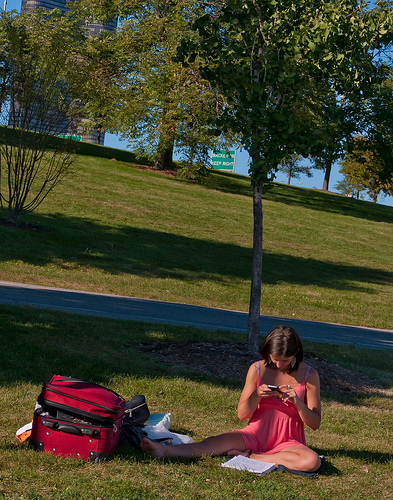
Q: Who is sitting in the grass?
A: A woman in a pink dress.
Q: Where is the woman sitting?
A: In the grass.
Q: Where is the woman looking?
A: At a cell phone.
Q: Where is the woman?
A: In a park.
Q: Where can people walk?
A: On the paved pathway.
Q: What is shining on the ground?
A: Sunlight.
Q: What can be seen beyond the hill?
A: A street sign.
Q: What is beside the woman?
A: A luggage case.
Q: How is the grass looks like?
A: Good.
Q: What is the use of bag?
A: To store items.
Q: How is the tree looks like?
A: Skinny brown bare tree.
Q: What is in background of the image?
A: Tall tree.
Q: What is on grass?
A: Mound of bark.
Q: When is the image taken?
A: When trees has leaves.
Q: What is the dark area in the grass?
A: A shadow.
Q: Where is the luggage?
A: On the ground.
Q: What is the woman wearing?
A: A pink dress.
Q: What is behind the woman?
A: A tree.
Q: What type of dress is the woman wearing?
A: A sundress.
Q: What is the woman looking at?
A: A cellphone.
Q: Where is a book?
A: On grass in front of a woman.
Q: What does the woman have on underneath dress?
A: A white bra.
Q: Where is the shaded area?
A: Under the trees.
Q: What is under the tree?
A: Wood chips.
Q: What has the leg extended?
A: The woman.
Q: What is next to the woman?
A: A suitcase.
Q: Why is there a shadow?
A: It is sunny.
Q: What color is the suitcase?
A: Red.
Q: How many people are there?
A: One.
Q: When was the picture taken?
A: Daytime.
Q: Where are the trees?
A: On the hill.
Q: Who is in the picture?
A: The woman.